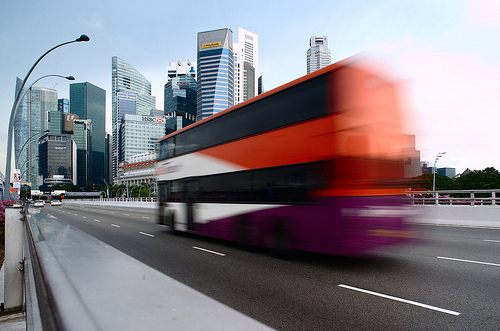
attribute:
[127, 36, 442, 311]
bus — double decker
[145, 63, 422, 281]
bus — red, white, purple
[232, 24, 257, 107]
building — tall, distant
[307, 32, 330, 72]
building — tall, distant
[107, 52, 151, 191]
building — tall, distant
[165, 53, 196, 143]
building — tall, distant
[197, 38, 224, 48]
sign — yellow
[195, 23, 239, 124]
building — tall, distant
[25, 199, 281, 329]
sidewalk — gray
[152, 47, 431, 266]
bus — driving on street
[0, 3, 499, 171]
sky — clear, blue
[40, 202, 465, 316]
lines — broken, white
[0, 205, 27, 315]
white pillar — by edge of overpass and lower ground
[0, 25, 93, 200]
curved lampposts — over roadway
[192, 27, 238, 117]
angled building — with blue and white stripes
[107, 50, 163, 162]
building — with curved roof over rectangular buildings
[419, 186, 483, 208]
partition/railing — behind bus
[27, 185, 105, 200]
overpass — crossing over top of roadway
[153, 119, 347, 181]
white/red stripe — between black bus windows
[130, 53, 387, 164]
bus top — red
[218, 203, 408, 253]
bus trim — purple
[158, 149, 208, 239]
bus front — white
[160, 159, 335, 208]
bottom row — windows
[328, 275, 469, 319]
white line — on street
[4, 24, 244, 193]
skyscrapers — in background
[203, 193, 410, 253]
lower bus — purple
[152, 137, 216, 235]
bus front — white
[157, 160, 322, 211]
lower windows — on bus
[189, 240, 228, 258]
white line — on street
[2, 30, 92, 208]
light pole — curved